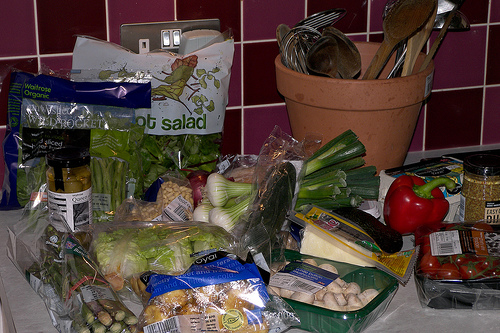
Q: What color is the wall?
A: Red and white.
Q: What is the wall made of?
A: Tile.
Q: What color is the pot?
A: Orange.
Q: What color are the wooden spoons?
A: Brown.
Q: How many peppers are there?
A: One.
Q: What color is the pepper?
A: Red and green.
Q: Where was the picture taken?
A: In a house.